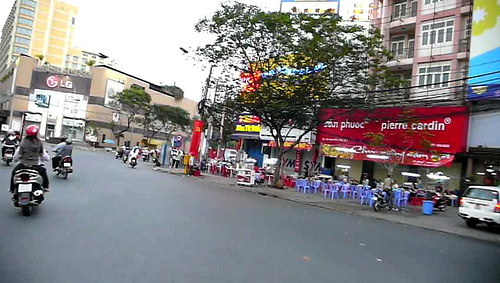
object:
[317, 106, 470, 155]
covering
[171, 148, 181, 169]
person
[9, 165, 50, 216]
bike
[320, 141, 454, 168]
banner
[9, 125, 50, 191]
girl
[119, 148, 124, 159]
person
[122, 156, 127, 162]
motorcycle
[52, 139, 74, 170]
person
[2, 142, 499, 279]
road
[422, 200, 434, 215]
bin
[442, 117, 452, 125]
sign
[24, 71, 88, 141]
lg store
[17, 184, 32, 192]
license plate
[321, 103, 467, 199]
store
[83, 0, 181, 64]
sky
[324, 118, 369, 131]
sign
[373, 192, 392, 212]
motorcycle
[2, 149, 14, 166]
motorcycle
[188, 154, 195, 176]
person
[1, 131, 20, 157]
person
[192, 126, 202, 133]
sign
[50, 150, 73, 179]
bikes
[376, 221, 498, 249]
drive way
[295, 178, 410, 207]
blue chair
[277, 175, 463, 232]
sidewalk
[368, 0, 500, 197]
building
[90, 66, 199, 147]
building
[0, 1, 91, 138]
building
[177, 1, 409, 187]
tree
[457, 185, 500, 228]
car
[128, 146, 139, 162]
person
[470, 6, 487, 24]
flower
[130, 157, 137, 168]
motorcycle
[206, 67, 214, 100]
pole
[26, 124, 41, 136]
helmet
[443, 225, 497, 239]
driveway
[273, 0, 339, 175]
building